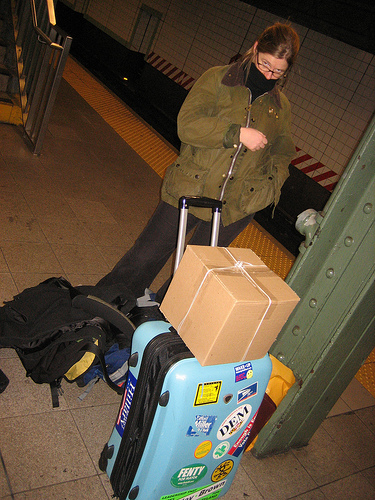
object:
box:
[159, 238, 300, 366]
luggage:
[93, 308, 275, 500]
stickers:
[214, 403, 252, 442]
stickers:
[195, 380, 221, 407]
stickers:
[235, 383, 260, 405]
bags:
[2, 275, 110, 390]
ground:
[1, 28, 374, 499]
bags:
[73, 297, 136, 389]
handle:
[172, 194, 226, 292]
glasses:
[254, 50, 289, 79]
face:
[252, 48, 288, 91]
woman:
[82, 20, 308, 311]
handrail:
[14, 3, 76, 156]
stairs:
[1, 2, 29, 127]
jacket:
[161, 54, 296, 229]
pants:
[82, 179, 256, 319]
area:
[42, 34, 296, 291]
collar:
[246, 61, 281, 99]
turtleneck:
[239, 59, 281, 105]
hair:
[235, 22, 299, 95]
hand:
[237, 126, 271, 151]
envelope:
[244, 350, 297, 459]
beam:
[252, 98, 375, 460]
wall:
[60, 2, 373, 194]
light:
[121, 72, 129, 83]